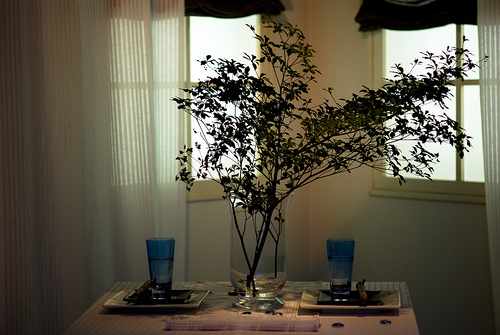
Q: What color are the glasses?
A: Blue.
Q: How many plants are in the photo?
A: 1.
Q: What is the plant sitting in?
A: A vase.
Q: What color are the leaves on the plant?
A: Green.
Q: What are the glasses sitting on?
A: Plates.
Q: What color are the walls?
A: White.